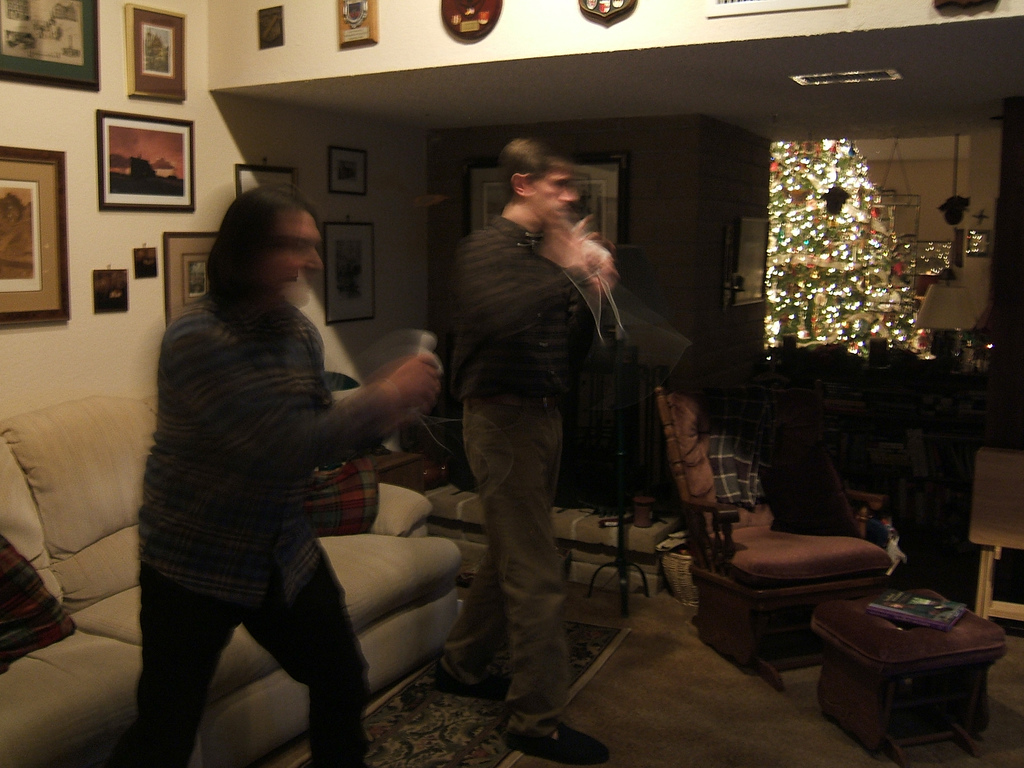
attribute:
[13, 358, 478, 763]
sofa — tan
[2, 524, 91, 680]
pillow — red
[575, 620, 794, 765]
rug — brown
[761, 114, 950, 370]
christmas tree — large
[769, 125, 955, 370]
christmas tree — decorated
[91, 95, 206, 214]
frame — black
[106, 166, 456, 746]
man — standing up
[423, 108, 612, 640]
man — standing up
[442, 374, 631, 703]
pants — brown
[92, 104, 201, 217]
picture — small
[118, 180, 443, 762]
man — in motion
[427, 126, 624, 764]
man — in motion, taller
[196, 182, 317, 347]
hair — long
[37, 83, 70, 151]
wall — white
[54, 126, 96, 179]
wall — white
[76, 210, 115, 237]
wall — white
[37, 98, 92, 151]
wall — white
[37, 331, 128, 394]
wall — white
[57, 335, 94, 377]
wall — white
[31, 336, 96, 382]
wall — white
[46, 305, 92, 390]
wall — white